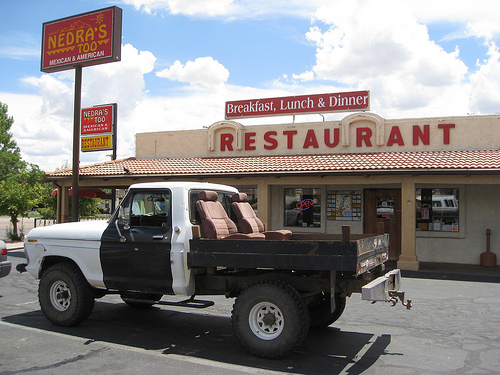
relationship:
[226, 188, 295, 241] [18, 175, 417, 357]
car seats in truck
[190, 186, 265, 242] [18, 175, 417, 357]
car seat in truck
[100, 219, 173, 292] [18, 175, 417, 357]
door on truck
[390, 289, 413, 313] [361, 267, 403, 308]
trailer hitch on bumper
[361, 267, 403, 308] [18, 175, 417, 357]
bumper on truck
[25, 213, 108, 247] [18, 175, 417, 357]
hood of truck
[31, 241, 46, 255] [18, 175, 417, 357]
gas cap on truck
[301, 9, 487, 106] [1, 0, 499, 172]
clouds in sky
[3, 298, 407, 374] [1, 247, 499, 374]
shadow on parking lot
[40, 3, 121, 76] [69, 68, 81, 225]
restaurant sign on pole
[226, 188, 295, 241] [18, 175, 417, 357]
car seats on truck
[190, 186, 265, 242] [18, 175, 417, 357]
car seat on truck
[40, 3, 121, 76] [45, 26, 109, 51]
restaurant sign with yellow writing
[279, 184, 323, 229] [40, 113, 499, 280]
window of restaurant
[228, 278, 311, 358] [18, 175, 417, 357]
back tire of truck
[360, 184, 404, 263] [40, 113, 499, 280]
door of restaurant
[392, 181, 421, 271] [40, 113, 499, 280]
pillar on restaurant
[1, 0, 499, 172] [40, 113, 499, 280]
sky above restaurant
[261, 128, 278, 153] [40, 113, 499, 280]
letter s on restaurant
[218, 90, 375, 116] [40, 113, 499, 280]
restaurant sign above restaurant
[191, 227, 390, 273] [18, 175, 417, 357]
bed of truck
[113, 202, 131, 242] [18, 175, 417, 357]
side mirror on truck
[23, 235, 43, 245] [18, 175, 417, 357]
front left flasher on truck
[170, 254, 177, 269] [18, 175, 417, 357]
dent on truck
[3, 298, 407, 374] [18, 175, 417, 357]
shadow of truck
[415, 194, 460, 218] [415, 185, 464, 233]
car reflection in window